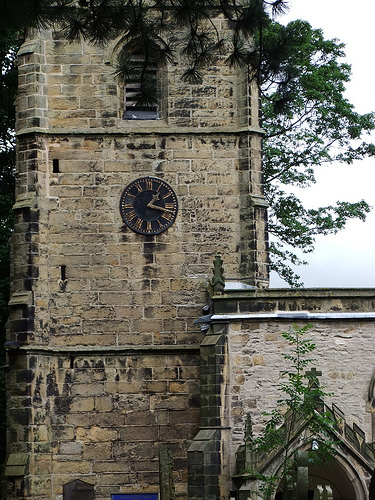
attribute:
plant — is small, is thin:
[240, 323, 335, 498]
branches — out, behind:
[257, 37, 284, 62]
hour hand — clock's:
[145, 189, 162, 207]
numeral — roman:
[145, 179, 154, 190]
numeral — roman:
[132, 182, 144, 198]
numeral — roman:
[125, 190, 136, 199]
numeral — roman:
[121, 208, 137, 222]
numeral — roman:
[142, 218, 156, 235]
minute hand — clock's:
[145, 201, 175, 218]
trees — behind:
[256, 6, 373, 288]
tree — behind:
[129, 0, 298, 84]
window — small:
[115, 40, 162, 119]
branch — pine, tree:
[27, 2, 275, 147]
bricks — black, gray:
[187, 148, 230, 196]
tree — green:
[286, 334, 306, 407]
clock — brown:
[112, 162, 205, 256]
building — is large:
[3, 9, 374, 498]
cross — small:
[292, 358, 340, 399]